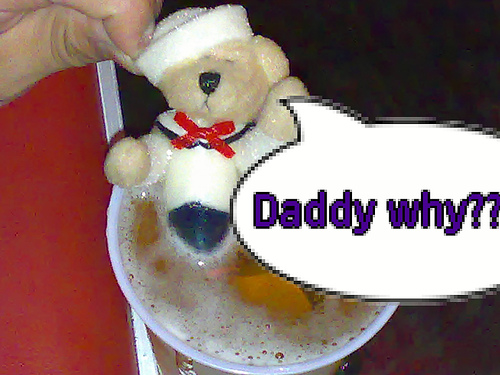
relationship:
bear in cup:
[108, 4, 316, 270] [122, 96, 434, 371]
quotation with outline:
[250, 188, 498, 234] [219, 97, 490, 319]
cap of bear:
[134, 6, 256, 81] [108, 4, 316, 270]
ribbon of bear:
[174, 113, 236, 159] [108, 4, 316, 270]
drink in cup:
[102, 100, 405, 374] [122, 96, 434, 371]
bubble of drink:
[242, 339, 295, 362] [102, 100, 405, 374]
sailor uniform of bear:
[140, 109, 259, 261] [108, 4, 316, 270]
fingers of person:
[1, 2, 157, 104] [1, 2, 163, 120]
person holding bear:
[1, 2, 163, 120] [108, 4, 316, 270]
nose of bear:
[196, 72, 222, 94] [108, 4, 316, 270]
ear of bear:
[252, 32, 295, 85] [108, 4, 316, 270]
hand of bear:
[258, 80, 314, 134] [108, 4, 316, 270]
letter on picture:
[249, 190, 495, 231] [3, 2, 497, 374]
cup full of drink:
[122, 96, 434, 371] [102, 100, 405, 374]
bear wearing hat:
[108, 4, 316, 270] [134, 6, 256, 81]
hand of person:
[1, 2, 157, 104] [1, 2, 163, 120]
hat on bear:
[134, 6, 256, 81] [108, 4, 316, 270]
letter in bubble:
[249, 190, 281, 234] [206, 88, 499, 329]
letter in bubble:
[249, 190, 281, 234] [242, 339, 295, 362]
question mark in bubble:
[465, 187, 490, 237] [206, 88, 499, 329]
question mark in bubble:
[465, 187, 490, 237] [242, 339, 295, 362]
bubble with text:
[206, 88, 499, 329] [252, 189, 499, 242]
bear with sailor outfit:
[108, 4, 316, 270] [140, 109, 259, 261]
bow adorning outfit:
[174, 113, 236, 159] [140, 109, 259, 261]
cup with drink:
[122, 96, 434, 371] [102, 100, 405, 374]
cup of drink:
[122, 96, 434, 371] [102, 100, 405, 374]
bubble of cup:
[240, 126, 496, 296] [122, 96, 434, 371]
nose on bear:
[196, 72, 222, 94] [108, 4, 316, 270]